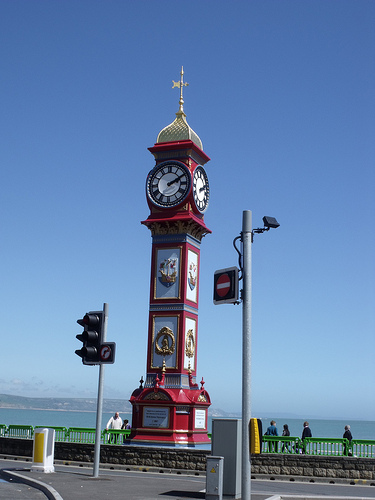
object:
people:
[342, 423, 355, 457]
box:
[205, 455, 226, 499]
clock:
[192, 164, 209, 215]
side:
[180, 129, 203, 387]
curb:
[125, 464, 180, 475]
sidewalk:
[107, 450, 210, 484]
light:
[77, 314, 100, 327]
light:
[76, 330, 99, 342]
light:
[75, 346, 98, 359]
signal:
[74, 310, 102, 363]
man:
[105, 411, 123, 445]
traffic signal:
[100, 344, 111, 359]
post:
[91, 364, 104, 477]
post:
[101, 303, 108, 342]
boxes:
[211, 418, 242, 499]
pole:
[241, 209, 252, 499]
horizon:
[0, 11, 373, 446]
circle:
[216, 273, 230, 297]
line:
[217, 282, 231, 289]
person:
[281, 423, 293, 455]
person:
[266, 420, 278, 452]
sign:
[214, 271, 237, 300]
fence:
[1, 422, 374, 461]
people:
[292, 421, 313, 454]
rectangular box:
[262, 215, 280, 229]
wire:
[233, 233, 243, 281]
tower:
[126, 63, 213, 453]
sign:
[99, 344, 113, 363]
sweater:
[107, 416, 124, 432]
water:
[0, 408, 373, 453]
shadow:
[158, 490, 206, 496]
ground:
[0, 461, 374, 498]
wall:
[2, 436, 374, 484]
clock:
[146, 159, 192, 209]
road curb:
[251, 474, 374, 488]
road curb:
[98, 461, 202, 477]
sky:
[3, 3, 372, 419]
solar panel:
[262, 216, 280, 228]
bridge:
[75, 392, 251, 488]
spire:
[156, 63, 204, 151]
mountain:
[1, 385, 94, 410]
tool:
[170, 61, 191, 118]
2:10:
[166, 170, 187, 187]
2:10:
[199, 183, 208, 194]